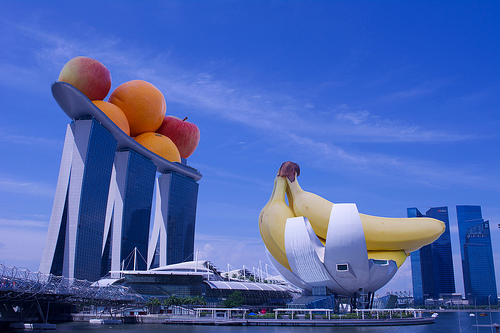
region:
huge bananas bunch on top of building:
[251, 154, 454, 279]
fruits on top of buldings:
[67, 52, 215, 172]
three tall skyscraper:
[43, 118, 213, 292]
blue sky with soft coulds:
[259, 64, 438, 161]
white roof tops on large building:
[84, 237, 299, 307]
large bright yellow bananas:
[267, 157, 454, 264]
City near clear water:
[393, 278, 492, 330]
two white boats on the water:
[428, 307, 453, 324]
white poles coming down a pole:
[109, 241, 159, 276]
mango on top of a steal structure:
[62, 59, 110, 106]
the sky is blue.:
[5, 3, 491, 288]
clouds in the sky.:
[7, 5, 487, 277]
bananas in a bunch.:
[262, 155, 430, 290]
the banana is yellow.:
[247, 154, 447, 279]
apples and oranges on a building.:
[56, 50, 198, 164]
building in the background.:
[398, 190, 494, 317]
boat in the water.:
[135, 295, 434, 327]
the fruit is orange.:
[106, 75, 169, 131]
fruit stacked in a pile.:
[52, 41, 201, 161]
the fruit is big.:
[50, 40, 449, 287]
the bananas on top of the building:
[253, 145, 449, 280]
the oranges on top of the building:
[85, 82, 189, 161]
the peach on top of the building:
[36, 43, 116, 105]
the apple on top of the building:
[166, 114, 205, 159]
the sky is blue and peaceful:
[286, 28, 474, 120]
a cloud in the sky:
[126, 47, 405, 165]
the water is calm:
[438, 305, 470, 329]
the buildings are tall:
[392, 198, 496, 307]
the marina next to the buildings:
[133, 305, 440, 330]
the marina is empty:
[134, 299, 473, 327]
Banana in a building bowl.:
[257, 157, 447, 289]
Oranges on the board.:
[57, 43, 216, 181]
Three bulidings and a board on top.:
[53, 46, 205, 283]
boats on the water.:
[431, 308, 494, 321]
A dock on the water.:
[175, 313, 435, 330]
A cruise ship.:
[97, 250, 291, 309]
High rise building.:
[406, 203, 498, 309]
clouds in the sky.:
[227, 66, 451, 152]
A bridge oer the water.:
[3, 268, 150, 315]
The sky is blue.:
[285, 14, 450, 85]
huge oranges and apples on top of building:
[45, 47, 222, 178]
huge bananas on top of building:
[260, 155, 420, 295]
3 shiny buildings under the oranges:
[55, 108, 205, 283]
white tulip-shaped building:
[250, 200, 409, 304]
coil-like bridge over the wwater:
[2, 266, 148, 303]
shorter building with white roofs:
[109, 260, 306, 299]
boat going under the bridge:
[11, 311, 75, 328]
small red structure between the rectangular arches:
[257, 307, 272, 322]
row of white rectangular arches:
[185, 302, 424, 322]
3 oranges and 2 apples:
[53, 48, 198, 177]